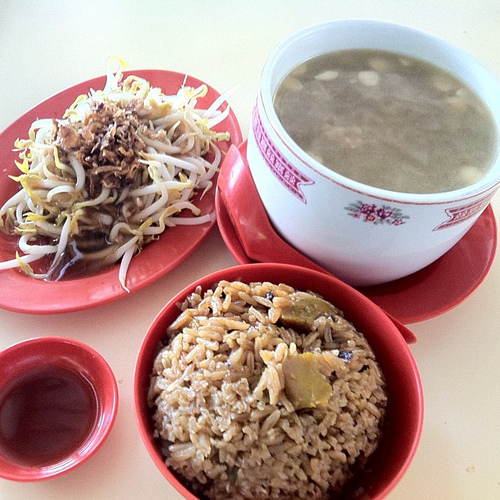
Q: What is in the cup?
A: Alphabet soup.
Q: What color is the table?
A: White.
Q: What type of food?
A: Chinese.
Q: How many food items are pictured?
A: Four.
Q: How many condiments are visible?
A: One.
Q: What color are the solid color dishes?
A: Red.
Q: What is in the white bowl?
A: Soup.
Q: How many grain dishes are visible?
A: One.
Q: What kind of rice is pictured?
A: Brown rice.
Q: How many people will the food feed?
A: One.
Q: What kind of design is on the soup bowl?
A: Floral.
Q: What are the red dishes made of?
A: Plastic.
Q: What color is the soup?
A: Grey.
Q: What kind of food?
A: Chinese.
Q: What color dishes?
A: Red.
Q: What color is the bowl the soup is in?
A: White.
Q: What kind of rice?
A: Fried.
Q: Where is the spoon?
A: Beside the soup.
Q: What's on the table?
A: Food.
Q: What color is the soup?
A: Brown.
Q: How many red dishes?
A: 5.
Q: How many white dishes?
A: 1.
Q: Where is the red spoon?
A: On the dish.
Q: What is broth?
A: The soup.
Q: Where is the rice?
A: In the bowl.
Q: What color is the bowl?
A: Red.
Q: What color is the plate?
A: Red.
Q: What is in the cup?
A: Soup.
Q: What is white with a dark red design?
A: The cup.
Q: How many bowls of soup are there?
A: One.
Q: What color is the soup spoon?
A: Red.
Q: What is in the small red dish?
A: Sauce.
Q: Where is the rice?
A: In the bottom red bowl.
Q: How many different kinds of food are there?
A: Three.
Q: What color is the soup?
A: Brown.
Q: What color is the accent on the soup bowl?
A: Red.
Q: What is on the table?
A: Food.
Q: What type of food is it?
A: Asian.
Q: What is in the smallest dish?
A: Sauce.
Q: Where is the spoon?
A: Next to the soup.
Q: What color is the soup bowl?
A: White.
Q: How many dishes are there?
A: Four.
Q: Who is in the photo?
A: No one.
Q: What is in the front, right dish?
A: Rice.